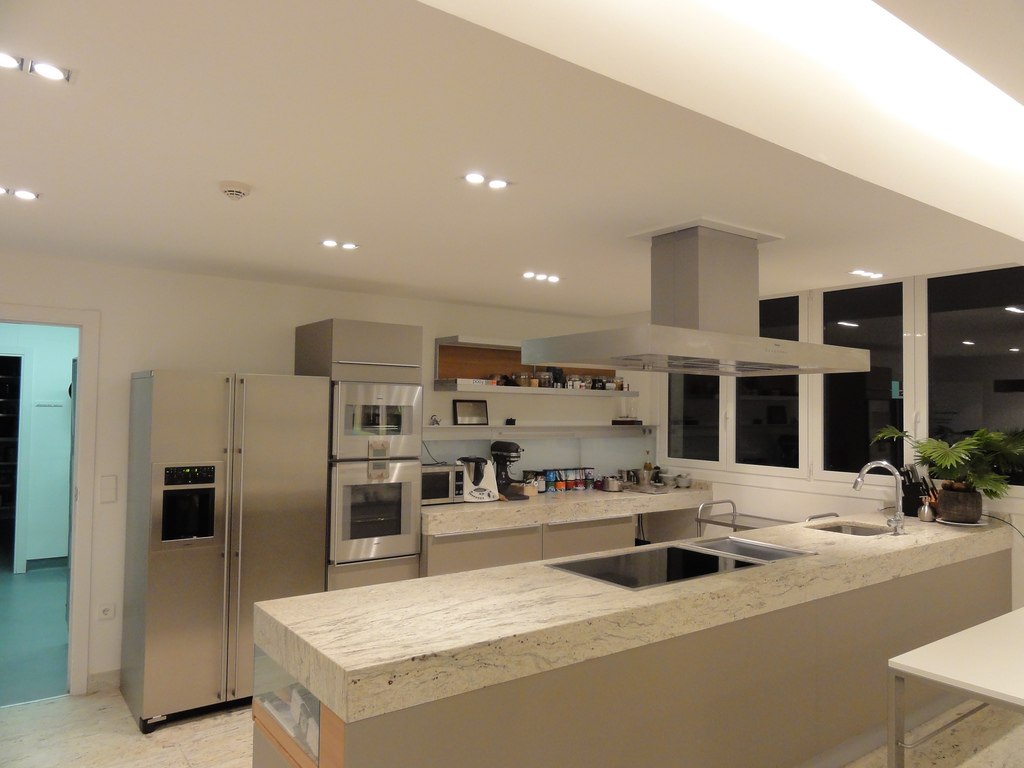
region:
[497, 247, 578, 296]
light in the ceiling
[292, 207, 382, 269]
light in the ceiling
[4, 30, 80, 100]
light in the ceiling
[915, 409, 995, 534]
plant on a counter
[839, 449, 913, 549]
faucet on a sink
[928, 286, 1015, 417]
window in a kitchen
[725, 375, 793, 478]
window in a kitchen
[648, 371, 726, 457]
window in a kitchen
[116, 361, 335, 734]
The silver, double door refrigerator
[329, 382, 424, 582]
The silver over next to the refrigerator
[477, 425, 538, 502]
The black mixer on the counter top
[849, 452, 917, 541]
The silver faucet over the sink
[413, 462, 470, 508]
The silver microwave on the countertop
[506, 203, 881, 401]
The large vent heading into the ceiling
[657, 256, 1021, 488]
The four windows at the end of the kitchen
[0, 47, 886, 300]
The lights in the ceiling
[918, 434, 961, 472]
green leaves on the plant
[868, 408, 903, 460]
green leaves on the plant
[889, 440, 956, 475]
green leaves on the plant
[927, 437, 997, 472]
green leaves on the plant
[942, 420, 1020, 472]
green leaves on the plant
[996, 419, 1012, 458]
green leaves on the plant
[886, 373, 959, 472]
green leaves on the plant